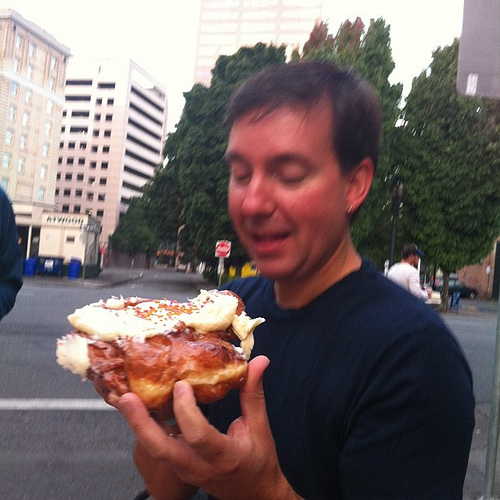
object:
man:
[104, 60, 477, 500]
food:
[54, 288, 267, 424]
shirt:
[130, 252, 476, 500]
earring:
[348, 204, 353, 214]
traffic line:
[0, 395, 121, 411]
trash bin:
[68, 258, 82, 279]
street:
[0, 269, 500, 499]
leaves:
[447, 166, 453, 171]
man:
[387, 242, 433, 303]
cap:
[402, 243, 426, 258]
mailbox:
[449, 290, 461, 310]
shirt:
[385, 262, 430, 304]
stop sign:
[214, 240, 231, 258]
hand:
[104, 354, 285, 500]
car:
[177, 262, 194, 272]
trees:
[391, 33, 500, 314]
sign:
[41, 213, 88, 228]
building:
[36, 211, 104, 279]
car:
[427, 276, 480, 300]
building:
[190, 0, 325, 91]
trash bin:
[23, 257, 36, 277]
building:
[453, 237, 500, 301]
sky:
[0, 1, 464, 172]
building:
[53, 57, 171, 269]